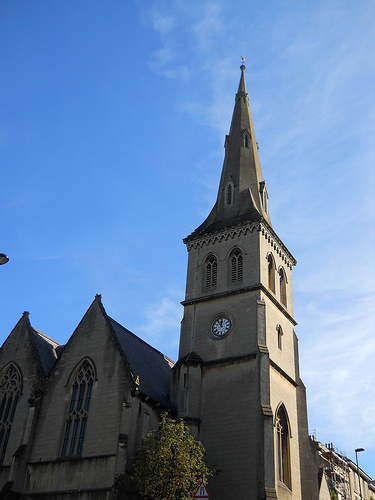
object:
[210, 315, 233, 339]
clock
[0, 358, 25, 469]
window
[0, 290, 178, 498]
side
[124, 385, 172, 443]
detail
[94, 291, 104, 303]
detail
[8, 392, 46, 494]
detail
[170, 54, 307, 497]
steeple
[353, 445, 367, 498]
light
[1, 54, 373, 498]
building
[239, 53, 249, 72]
vane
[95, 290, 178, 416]
roof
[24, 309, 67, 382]
roof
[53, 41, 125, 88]
part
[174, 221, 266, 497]
wall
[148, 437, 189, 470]
part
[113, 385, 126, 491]
edge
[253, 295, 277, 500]
edge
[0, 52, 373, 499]
church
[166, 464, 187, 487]
part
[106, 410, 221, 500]
tree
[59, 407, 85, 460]
part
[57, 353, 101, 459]
window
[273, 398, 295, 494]
window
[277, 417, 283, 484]
part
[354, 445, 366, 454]
part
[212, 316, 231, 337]
face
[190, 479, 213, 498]
sign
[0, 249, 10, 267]
street light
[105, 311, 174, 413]
shadow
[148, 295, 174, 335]
clouds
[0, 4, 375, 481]
sky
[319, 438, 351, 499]
scaffolding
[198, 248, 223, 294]
windows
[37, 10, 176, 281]
sky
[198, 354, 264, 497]
wall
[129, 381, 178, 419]
edge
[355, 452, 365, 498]
post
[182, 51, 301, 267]
top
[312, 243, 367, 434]
cloud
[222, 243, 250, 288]
windows